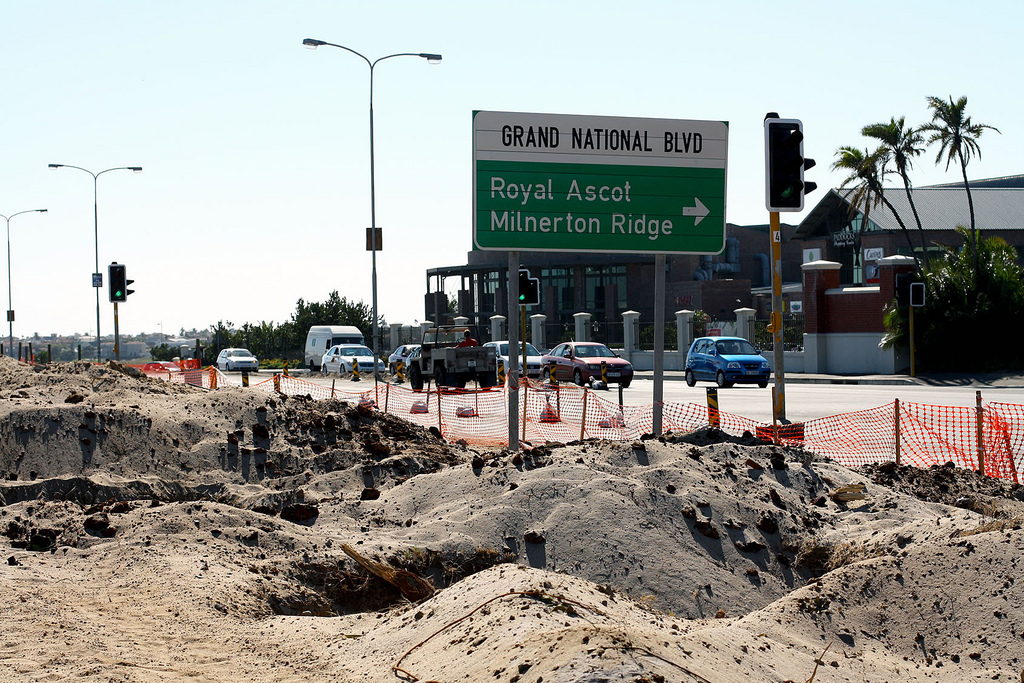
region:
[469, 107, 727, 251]
green and white sign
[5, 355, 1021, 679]
some piles of sand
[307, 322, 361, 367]
the van is white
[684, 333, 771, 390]
the car is blue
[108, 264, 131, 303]
the light is black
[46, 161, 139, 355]
the light is double headed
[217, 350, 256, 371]
car on the road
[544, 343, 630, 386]
the car is red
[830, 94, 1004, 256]
a group of palm trees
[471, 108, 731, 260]
a green and white directional sign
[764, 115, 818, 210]
an electric traffic signal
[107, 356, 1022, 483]
portable fencing net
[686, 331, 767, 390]
a blue car in street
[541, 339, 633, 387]
a red car in street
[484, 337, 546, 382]
a white car in street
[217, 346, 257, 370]
a white car in street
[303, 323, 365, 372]
a large white truck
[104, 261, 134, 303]
an electric traffic signal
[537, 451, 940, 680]
a big pile of sand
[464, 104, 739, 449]
a street or road sign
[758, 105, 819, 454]
a traffic light post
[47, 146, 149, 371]
a street light next to a traffic light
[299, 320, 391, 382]
a big van behind a car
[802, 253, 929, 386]
a piece of a wall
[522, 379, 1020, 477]
a portion of an orange netting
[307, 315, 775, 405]
different vehicles on a street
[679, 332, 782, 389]
a blue subcompact vehicle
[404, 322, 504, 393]
an open roof vehicle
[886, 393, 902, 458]
small pole holding up orange fencing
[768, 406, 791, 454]
small pole holding up orange fencing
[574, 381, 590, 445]
small pole holding up orange fencing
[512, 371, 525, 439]
small pole holding up orange fencing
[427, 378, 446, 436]
small pole holding up orange fencing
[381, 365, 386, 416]
small pole holding up orange fencing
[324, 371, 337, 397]
small pole holding up orange fencing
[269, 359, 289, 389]
small pole holding up orange fencing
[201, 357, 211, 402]
small pole holding up orange fencing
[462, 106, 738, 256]
green and white sign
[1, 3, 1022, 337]
light of dayime sky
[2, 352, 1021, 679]
dunes of light colored sand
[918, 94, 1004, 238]
leaves of palm tree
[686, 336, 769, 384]
front of blue compact car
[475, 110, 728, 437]
sign on two metal poles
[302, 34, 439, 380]
two street lights on one pole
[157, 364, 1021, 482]
sagging orange mesh fence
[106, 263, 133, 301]
glowing green traffic light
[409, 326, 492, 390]
back of convertible jeep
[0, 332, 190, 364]
haze on distant horizon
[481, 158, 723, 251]
a green and white sign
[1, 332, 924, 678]
piles of dirt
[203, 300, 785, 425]
cars on the road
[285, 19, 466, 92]
a pair of lights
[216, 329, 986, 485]
orange mesh next to dirt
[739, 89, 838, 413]
traffic light on pole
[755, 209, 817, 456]
the pole is yellow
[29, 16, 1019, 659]
a bright and sunny day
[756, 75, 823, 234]
the traffic light is black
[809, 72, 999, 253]
a set of trees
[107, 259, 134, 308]
an illuminated green traffic control light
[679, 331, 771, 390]
a small blue car